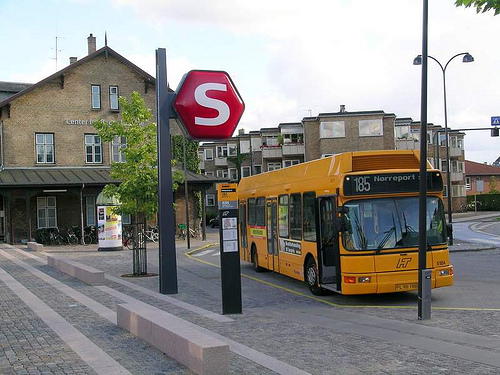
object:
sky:
[0, 0, 497, 168]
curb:
[199, 242, 499, 342]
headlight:
[358, 276, 371, 283]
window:
[35, 132, 55, 164]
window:
[84, 132, 103, 164]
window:
[90, 84, 102, 111]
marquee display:
[353, 174, 416, 193]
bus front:
[337, 148, 454, 295]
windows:
[247, 195, 267, 227]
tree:
[90, 91, 187, 276]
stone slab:
[116, 297, 230, 373]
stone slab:
[47, 255, 106, 287]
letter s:
[194, 82, 231, 126]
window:
[302, 190, 317, 242]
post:
[216, 183, 243, 314]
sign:
[173, 70, 245, 140]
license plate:
[395, 282, 418, 290]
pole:
[154, 45, 178, 294]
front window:
[340, 195, 448, 250]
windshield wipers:
[376, 211, 398, 253]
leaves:
[453, 0, 500, 17]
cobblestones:
[0, 330, 54, 375]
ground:
[1, 241, 93, 374]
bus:
[237, 149, 454, 296]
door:
[238, 200, 248, 262]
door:
[315, 193, 340, 292]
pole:
[181, 135, 190, 249]